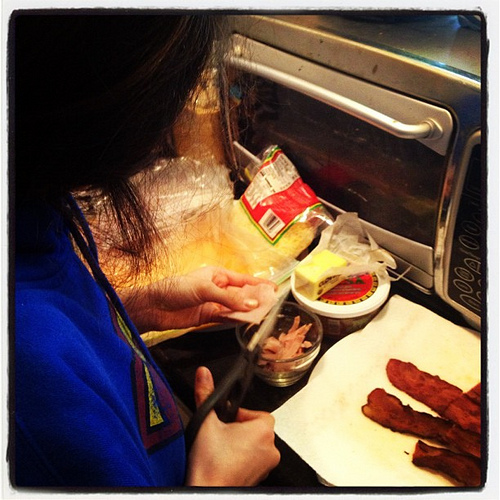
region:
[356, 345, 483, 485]
Strips of delicious bacon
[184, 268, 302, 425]
Pair of scissors with black handle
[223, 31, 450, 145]
Vertical bar handle on oven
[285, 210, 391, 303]
Partial stick of butter in white wrapper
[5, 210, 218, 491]
blue shirt with red and yellow emblem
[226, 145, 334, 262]
Shredded cheese in bag to left of butter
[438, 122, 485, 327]
Touch controls of oven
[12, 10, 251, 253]
Dark hair of person cutting meat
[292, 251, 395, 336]
Round container with SA visible under butter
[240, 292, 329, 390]
Small round container of cut up meat strips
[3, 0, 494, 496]
a digital frame is applied to this picture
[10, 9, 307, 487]
the woman is cutting food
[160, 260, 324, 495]
the woman is holding scissors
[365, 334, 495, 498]
bacon is on a paper towel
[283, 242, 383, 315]
the butter is on top of a container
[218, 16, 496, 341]
the toaster oven is gray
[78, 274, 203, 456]
a superman logo is on the woman's shirt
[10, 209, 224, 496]
the woman's shirt is blue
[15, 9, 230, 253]
the woman's hair is black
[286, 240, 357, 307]
the butter is yellow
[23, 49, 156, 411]
this is a lady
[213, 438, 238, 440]
the lady has light skin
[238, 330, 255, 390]
this is a scissor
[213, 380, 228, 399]
the handle is black in color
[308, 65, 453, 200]
this is a microwave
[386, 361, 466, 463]
this is a beef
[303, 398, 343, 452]
this is a paper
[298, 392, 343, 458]
the paper is white in color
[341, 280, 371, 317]
this is a container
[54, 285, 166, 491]
this is a pullover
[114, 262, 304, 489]
hands cutting strips of ham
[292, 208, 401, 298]
unwrapped partial stick of yellow butter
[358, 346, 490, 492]
cooked red and brown bacon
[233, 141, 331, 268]
plastic bag of shredded cheese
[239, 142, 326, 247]
red, white, and green food label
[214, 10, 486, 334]
stainless steel microwave oven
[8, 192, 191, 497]
blue superman sweater with red and yellow logo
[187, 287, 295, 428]
metal scissors with black plastic handle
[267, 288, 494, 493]
white paper towel sheet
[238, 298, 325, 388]
cup of sliced ham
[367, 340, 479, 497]
This is bacon resting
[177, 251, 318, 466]
The woman has scissors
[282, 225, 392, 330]
This butter is open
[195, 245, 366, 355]
The woman is cutting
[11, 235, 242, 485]
She has on a blue shirt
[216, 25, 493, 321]
The oven is metal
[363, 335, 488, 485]
The bacon is cooked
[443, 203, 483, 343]
The oven has buttons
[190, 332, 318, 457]
The scissors are black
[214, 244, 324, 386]
She is cutting meat